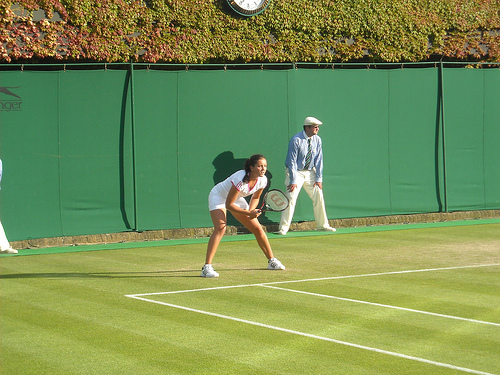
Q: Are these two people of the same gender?
A: No, they are both male and female.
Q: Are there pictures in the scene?
A: No, there are no pictures.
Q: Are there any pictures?
A: No, there are no pictures.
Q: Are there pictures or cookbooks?
A: No, there are no pictures or cookbooks.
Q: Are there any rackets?
A: Yes, there is a racket.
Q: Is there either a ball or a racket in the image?
A: Yes, there is a racket.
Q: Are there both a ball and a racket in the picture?
A: No, there is a racket but no balls.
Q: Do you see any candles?
A: No, there are no candles.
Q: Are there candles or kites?
A: No, there are no candles or kites.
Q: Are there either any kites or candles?
A: No, there are no candles or kites.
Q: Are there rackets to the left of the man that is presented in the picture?
A: Yes, there is a racket to the left of the man.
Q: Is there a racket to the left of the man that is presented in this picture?
A: Yes, there is a racket to the left of the man.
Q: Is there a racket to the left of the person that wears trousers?
A: Yes, there is a racket to the left of the man.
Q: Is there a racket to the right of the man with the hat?
A: No, the racket is to the left of the man.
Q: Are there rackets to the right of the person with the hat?
A: No, the racket is to the left of the man.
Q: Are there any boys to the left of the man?
A: No, there is a racket to the left of the man.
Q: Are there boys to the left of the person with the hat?
A: No, there is a racket to the left of the man.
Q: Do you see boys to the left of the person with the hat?
A: No, there is a racket to the left of the man.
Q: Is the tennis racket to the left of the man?
A: Yes, the tennis racket is to the left of the man.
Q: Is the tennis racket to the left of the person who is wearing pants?
A: Yes, the tennis racket is to the left of the man.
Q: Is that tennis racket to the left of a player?
A: No, the tennis racket is to the left of the man.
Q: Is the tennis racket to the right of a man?
A: No, the tennis racket is to the left of a man.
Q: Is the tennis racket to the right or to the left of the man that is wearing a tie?
A: The tennis racket is to the left of the man.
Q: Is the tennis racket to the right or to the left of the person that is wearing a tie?
A: The tennis racket is to the left of the man.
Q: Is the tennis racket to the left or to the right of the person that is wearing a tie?
A: The tennis racket is to the left of the man.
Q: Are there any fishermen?
A: No, there are no fishermen.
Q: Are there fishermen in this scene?
A: No, there are no fishermen.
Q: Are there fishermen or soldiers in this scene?
A: No, there are no fishermen or soldiers.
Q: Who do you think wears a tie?
A: The man wears a tie.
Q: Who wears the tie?
A: The man wears a tie.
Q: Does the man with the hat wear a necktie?
A: Yes, the man wears a necktie.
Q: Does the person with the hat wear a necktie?
A: Yes, the man wears a necktie.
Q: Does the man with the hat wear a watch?
A: No, the man wears a necktie.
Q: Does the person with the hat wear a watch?
A: No, the man wears a necktie.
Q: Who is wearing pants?
A: The man is wearing pants.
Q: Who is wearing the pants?
A: The man is wearing pants.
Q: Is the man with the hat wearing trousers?
A: Yes, the man is wearing trousers.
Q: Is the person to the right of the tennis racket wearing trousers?
A: Yes, the man is wearing trousers.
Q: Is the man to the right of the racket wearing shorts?
A: No, the man is wearing trousers.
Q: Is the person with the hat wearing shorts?
A: No, the man is wearing trousers.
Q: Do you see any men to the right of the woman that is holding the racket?
A: Yes, there is a man to the right of the woman.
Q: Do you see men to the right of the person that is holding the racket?
A: Yes, there is a man to the right of the woman.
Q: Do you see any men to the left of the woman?
A: No, the man is to the right of the woman.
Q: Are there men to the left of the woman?
A: No, the man is to the right of the woman.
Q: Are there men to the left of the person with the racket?
A: No, the man is to the right of the woman.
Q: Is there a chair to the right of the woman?
A: No, there is a man to the right of the woman.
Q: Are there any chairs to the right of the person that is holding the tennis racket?
A: No, there is a man to the right of the woman.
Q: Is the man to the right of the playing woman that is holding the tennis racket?
A: Yes, the man is to the right of the woman.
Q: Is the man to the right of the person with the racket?
A: Yes, the man is to the right of the woman.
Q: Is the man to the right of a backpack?
A: No, the man is to the right of the woman.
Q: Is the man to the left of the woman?
A: No, the man is to the right of the woman.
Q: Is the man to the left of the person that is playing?
A: No, the man is to the right of the woman.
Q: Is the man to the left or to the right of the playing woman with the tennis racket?
A: The man is to the right of the woman.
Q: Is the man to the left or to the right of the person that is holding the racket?
A: The man is to the right of the woman.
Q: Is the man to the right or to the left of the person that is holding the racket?
A: The man is to the right of the woman.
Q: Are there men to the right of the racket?
A: Yes, there is a man to the right of the racket.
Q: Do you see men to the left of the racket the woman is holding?
A: No, the man is to the right of the tennis racket.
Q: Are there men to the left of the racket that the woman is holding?
A: No, the man is to the right of the tennis racket.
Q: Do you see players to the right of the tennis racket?
A: No, there is a man to the right of the tennis racket.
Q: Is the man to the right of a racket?
A: Yes, the man is to the right of a racket.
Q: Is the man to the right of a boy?
A: No, the man is to the right of a racket.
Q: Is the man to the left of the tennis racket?
A: No, the man is to the right of the tennis racket.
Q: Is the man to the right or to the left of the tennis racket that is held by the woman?
A: The man is to the right of the tennis racket.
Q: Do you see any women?
A: Yes, there is a woman.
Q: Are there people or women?
A: Yes, there is a woman.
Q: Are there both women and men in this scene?
A: Yes, there are both a woman and a man.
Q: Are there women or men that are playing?
A: Yes, the woman is playing.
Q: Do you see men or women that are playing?
A: Yes, the woman is playing.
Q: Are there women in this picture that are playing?
A: Yes, there is a woman that is playing.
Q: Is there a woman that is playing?
A: Yes, there is a woman that is playing.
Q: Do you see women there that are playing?
A: Yes, there is a woman that is playing.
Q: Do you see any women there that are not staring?
A: Yes, there is a woman that is playing .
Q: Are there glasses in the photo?
A: No, there are no glasses.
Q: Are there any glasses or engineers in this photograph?
A: No, there are no glasses or engineers.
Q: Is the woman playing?
A: Yes, the woman is playing.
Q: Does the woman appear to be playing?
A: Yes, the woman is playing.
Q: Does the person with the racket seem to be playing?
A: Yes, the woman is playing.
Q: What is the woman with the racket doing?
A: The woman is playing.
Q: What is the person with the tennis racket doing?
A: The woman is playing.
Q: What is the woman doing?
A: The woman is playing.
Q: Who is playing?
A: The woman is playing.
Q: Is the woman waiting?
A: No, the woman is playing.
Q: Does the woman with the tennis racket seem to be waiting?
A: No, the woman is playing.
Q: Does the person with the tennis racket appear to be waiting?
A: No, the woman is playing.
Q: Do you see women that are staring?
A: No, there is a woman but she is playing.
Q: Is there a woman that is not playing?
A: No, there is a woman but she is playing.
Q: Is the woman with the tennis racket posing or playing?
A: The woman is playing.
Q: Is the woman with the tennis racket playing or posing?
A: The woman is playing.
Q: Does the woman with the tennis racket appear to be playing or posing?
A: The woman is playing.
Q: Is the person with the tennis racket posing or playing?
A: The woman is playing.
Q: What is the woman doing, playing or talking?
A: The woman is playing.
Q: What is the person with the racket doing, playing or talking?
A: The woman is playing.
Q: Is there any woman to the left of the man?
A: Yes, there is a woman to the left of the man.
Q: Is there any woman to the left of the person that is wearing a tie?
A: Yes, there is a woman to the left of the man.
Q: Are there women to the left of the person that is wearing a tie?
A: Yes, there is a woman to the left of the man.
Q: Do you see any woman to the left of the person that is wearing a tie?
A: Yes, there is a woman to the left of the man.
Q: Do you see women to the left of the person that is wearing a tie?
A: Yes, there is a woman to the left of the man.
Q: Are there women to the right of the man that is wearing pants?
A: No, the woman is to the left of the man.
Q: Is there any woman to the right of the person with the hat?
A: No, the woman is to the left of the man.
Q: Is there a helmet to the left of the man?
A: No, there is a woman to the left of the man.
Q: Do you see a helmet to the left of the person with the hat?
A: No, there is a woman to the left of the man.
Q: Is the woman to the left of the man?
A: Yes, the woman is to the left of the man.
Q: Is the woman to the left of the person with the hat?
A: Yes, the woman is to the left of the man.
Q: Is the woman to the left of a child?
A: No, the woman is to the left of the man.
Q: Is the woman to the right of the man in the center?
A: No, the woman is to the left of the man.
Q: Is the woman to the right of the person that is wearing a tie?
A: No, the woman is to the left of the man.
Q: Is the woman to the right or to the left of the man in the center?
A: The woman is to the left of the man.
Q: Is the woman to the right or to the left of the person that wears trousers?
A: The woman is to the left of the man.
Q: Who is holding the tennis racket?
A: The woman is holding the tennis racket.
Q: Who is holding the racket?
A: The woman is holding the tennis racket.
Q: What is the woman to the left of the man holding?
A: The woman is holding the racket.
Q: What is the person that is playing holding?
A: The woman is holding the racket.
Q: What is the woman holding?
A: The woman is holding the racket.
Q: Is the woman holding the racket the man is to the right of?
A: Yes, the woman is holding the racket.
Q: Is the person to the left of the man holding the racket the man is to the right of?
A: Yes, the woman is holding the racket.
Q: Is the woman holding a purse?
A: No, the woman is holding the racket.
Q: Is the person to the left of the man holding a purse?
A: No, the woman is holding the racket.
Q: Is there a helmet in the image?
A: No, there are no helmets.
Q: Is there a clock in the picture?
A: Yes, there is a clock.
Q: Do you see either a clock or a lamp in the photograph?
A: Yes, there is a clock.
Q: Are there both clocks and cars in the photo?
A: No, there is a clock but no cars.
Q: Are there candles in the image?
A: No, there are no candles.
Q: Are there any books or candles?
A: No, there are no candles or books.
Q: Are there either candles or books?
A: No, there are no candles or books.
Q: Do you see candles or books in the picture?
A: No, there are no candles or books.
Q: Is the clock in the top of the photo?
A: Yes, the clock is in the top of the image.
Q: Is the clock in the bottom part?
A: No, the clock is in the top of the image.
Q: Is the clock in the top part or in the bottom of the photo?
A: The clock is in the top of the image.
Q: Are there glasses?
A: No, there are no glasses.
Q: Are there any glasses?
A: No, there are no glasses.